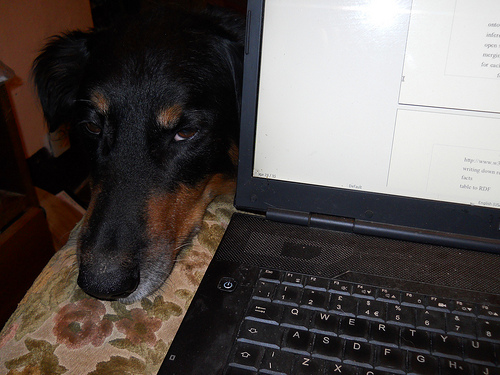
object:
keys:
[316, 332, 346, 356]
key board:
[216, 254, 499, 364]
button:
[219, 276, 233, 294]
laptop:
[160, 0, 500, 375]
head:
[30, 28, 246, 304]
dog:
[24, 0, 352, 364]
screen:
[253, 0, 499, 211]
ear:
[30, 29, 95, 136]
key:
[299, 279, 337, 315]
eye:
[172, 115, 209, 147]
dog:
[31, 0, 244, 304]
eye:
[76, 106, 105, 138]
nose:
[73, 264, 146, 296]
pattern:
[14, 295, 139, 373]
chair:
[1, 177, 235, 371]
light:
[251, 6, 498, 209]